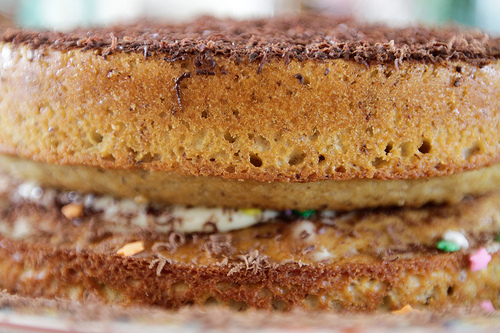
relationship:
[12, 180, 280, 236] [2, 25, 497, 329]
cream filling inside of cake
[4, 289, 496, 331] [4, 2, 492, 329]
plate holding cakes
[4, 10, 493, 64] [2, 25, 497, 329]
top on cake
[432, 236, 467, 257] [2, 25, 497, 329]
sprinkle on cake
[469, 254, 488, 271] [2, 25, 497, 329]
sprinkle on cake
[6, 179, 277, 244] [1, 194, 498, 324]
icing in between cake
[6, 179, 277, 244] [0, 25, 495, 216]
icing in between bread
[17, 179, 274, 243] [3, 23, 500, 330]
cream filling in creram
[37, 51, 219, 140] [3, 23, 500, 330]
crust on creram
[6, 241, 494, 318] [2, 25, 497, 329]
holes in cake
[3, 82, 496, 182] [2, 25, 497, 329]
holes in cake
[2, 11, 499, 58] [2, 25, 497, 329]
crust on cake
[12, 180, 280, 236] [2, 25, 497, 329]
cream filling on cake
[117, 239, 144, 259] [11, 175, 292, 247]
orange confetti in filling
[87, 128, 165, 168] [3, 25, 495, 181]
holes in bread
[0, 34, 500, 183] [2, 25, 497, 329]
crust of cake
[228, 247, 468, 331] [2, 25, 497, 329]
crust of cake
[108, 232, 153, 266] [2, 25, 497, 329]
sprinkle on cake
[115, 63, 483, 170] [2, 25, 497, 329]
layer on cake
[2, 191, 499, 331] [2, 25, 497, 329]
layer on cake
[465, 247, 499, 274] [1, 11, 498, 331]
sprinkle on dessert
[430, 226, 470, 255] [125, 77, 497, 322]
sprinkle on cake